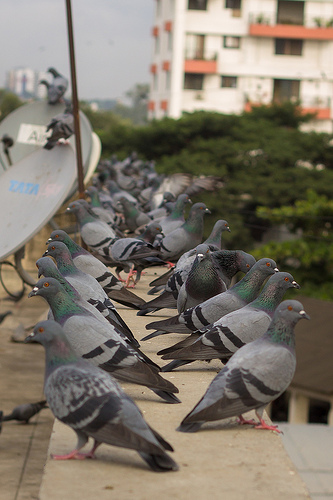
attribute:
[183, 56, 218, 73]
balcony — coral colored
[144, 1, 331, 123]
building — distant, white and orange 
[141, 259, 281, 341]
pigeon — grey black and green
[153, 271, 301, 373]
pigeon — grey black and green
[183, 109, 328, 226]
trees — full 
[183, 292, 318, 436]
pigeon — grey black and green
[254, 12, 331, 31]
plants — growing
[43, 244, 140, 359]
pigeon — grey, black, green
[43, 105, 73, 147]
pigeon — perched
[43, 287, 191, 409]
pigeon — grey, black, green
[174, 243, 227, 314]
pigeon — grey black and green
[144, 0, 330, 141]
building — multi story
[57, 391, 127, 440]
tripes — black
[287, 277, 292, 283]
eye — red 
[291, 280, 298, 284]
beak — white 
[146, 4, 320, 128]
hi-rise — tan 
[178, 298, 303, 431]
pigeon — perched 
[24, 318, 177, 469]
pigeon — perched 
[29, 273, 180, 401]
pigeon — perched 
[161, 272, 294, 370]
pigeon — perched 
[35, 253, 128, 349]
pigeon — perched 